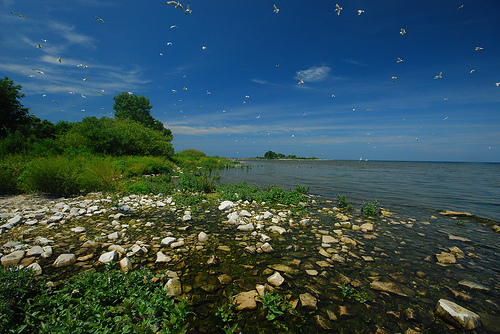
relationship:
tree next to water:
[112, 91, 173, 134] [0, 159, 499, 333]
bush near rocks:
[22, 154, 98, 198] [1, 195, 498, 333]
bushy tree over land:
[1, 78, 38, 138] [0, 154, 174, 178]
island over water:
[238, 150, 321, 163] [0, 159, 499, 333]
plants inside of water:
[215, 288, 291, 331] [0, 159, 499, 333]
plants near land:
[135, 176, 304, 207] [0, 154, 174, 178]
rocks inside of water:
[1, 195, 498, 333] [0, 159, 499, 333]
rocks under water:
[1, 195, 498, 333] [0, 159, 499, 333]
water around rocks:
[0, 159, 499, 333] [1, 195, 498, 333]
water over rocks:
[0, 159, 499, 333] [1, 195, 498, 333]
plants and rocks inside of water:
[3, 187, 499, 333] [0, 159, 499, 333]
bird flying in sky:
[332, 3, 344, 15] [5, 3, 495, 167]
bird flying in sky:
[272, 3, 280, 13] [5, 3, 495, 167]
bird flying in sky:
[357, 8, 365, 15] [5, 3, 495, 167]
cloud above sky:
[292, 60, 331, 86] [5, 3, 495, 167]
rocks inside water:
[1, 195, 498, 333] [0, 159, 499, 333]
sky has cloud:
[5, 3, 495, 167] [292, 60, 331, 86]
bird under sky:
[332, 3, 344, 15] [5, 3, 495, 167]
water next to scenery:
[0, 159, 499, 333] [8, 88, 355, 332]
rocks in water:
[0, 159, 499, 333] [212, 153, 499, 330]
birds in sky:
[5, 3, 495, 167] [5, 3, 495, 167]